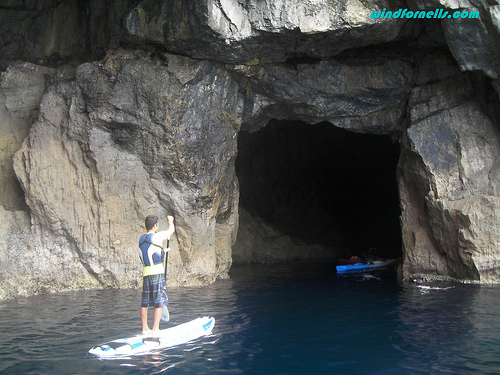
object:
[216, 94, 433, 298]
cave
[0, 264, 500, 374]
water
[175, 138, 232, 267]
stone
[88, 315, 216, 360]
board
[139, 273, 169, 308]
shorts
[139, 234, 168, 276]
shirt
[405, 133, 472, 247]
rock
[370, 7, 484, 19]
writing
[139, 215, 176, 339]
man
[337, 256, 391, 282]
canoe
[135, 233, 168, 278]
vest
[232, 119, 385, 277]
tunnel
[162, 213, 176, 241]
arm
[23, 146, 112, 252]
sunlight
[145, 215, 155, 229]
hair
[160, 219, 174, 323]
paddler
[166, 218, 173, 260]
handle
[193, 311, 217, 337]
edge